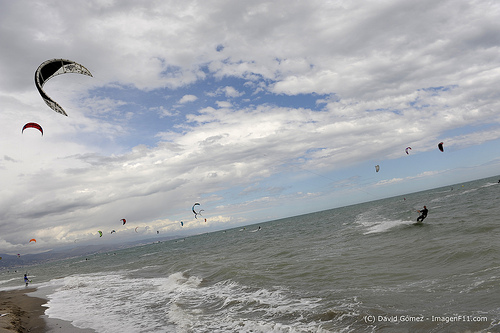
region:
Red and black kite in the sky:
[20, 123, 47, 137]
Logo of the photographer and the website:
[347, 310, 495, 325]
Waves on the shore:
[8, 271, 325, 331]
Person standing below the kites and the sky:
[19, 267, 34, 290]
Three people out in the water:
[217, 220, 262, 237]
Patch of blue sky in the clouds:
[76, 64, 341, 154]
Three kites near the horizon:
[366, 130, 458, 191]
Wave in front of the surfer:
[355, 212, 430, 239]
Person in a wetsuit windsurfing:
[412, 201, 434, 226]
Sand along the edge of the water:
[0, 278, 48, 331]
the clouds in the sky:
[342, 24, 442, 76]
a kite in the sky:
[23, 49, 113, 119]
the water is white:
[97, 277, 181, 318]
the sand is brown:
[7, 295, 27, 328]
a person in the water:
[398, 200, 441, 225]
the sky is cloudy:
[337, 32, 425, 97]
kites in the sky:
[178, 190, 218, 227]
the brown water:
[277, 231, 382, 288]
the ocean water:
[255, 225, 319, 270]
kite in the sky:
[20, 50, 116, 117]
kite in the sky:
[191, 201, 206, 221]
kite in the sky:
[435, 137, 455, 160]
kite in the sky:
[188, 200, 204, 215]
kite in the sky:
[118, 213, 135, 225]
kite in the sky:
[93, 228, 108, 240]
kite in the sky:
[27, 235, 49, 250]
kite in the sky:
[189, 213, 206, 220]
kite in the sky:
[93, 229, 107, 239]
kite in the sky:
[21, 233, 43, 245]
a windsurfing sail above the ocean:
[26, 48, 100, 118]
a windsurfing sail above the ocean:
[15, 120, 45, 140]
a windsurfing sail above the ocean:
[369, 162, 384, 174]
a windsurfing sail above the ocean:
[396, 141, 418, 166]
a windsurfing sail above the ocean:
[427, 135, 454, 160]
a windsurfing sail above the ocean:
[117, 215, 130, 228]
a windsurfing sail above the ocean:
[151, 221, 164, 238]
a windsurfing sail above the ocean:
[23, 233, 42, 246]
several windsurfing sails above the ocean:
[86, 200, 238, 253]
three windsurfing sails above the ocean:
[360, 130, 446, 179]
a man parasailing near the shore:
[36, 57, 428, 228]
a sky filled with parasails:
[17, 57, 460, 243]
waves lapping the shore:
[36, 272, 346, 329]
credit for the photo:
[350, 308, 497, 331]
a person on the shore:
[22, 272, 31, 290]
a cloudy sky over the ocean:
[0, 12, 497, 257]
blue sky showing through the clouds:
[77, 57, 319, 159]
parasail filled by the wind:
[34, 57, 94, 117]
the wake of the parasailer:
[343, 206, 418, 236]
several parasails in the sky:
[92, 200, 219, 244]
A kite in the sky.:
[26, 45, 104, 121]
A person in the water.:
[395, 191, 440, 226]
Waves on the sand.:
[42, 285, 132, 330]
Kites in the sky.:
[80, 192, 230, 227]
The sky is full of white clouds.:
[54, 12, 473, 99]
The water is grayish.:
[192, 238, 472, 305]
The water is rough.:
[139, 226, 463, 308]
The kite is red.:
[7, 115, 54, 142]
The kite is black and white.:
[22, 52, 102, 123]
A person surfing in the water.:
[402, 190, 444, 235]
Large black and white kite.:
[32, 57, 94, 117]